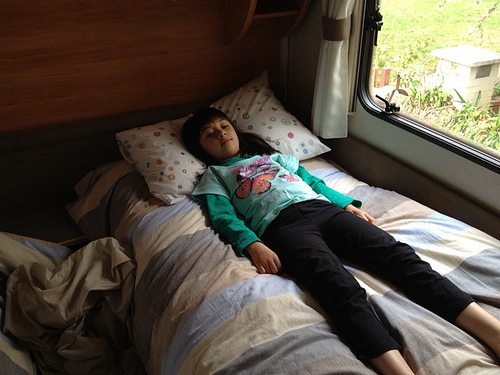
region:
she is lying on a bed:
[172, 100, 496, 366]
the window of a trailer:
[314, 4, 499, 197]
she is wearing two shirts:
[187, 137, 369, 279]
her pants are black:
[261, 193, 488, 373]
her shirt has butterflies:
[220, 163, 325, 211]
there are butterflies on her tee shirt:
[175, 93, 362, 303]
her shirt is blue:
[181, 130, 391, 279]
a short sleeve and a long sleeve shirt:
[173, 136, 363, 283]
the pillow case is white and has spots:
[122, 49, 333, 199]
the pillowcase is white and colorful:
[105, 47, 360, 216]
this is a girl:
[222, 130, 398, 255]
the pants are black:
[232, 232, 442, 374]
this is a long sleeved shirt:
[181, 103, 252, 295]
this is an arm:
[148, 195, 339, 312]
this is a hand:
[227, 238, 297, 303]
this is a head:
[150, 94, 254, 179]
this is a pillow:
[159, 151, 167, 180]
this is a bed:
[105, 231, 285, 372]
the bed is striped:
[199, 330, 237, 370]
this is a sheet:
[25, 230, 95, 327]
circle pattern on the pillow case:
[119, 78, 332, 203]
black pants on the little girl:
[268, 205, 475, 364]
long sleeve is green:
[201, 194, 260, 255]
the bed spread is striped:
[76, 159, 499, 374]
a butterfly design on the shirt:
[236, 172, 275, 198]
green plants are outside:
[377, 2, 499, 145]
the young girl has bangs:
[193, 109, 227, 134]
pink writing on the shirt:
[233, 156, 273, 180]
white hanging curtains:
[315, 1, 352, 137]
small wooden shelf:
[233, 0, 310, 41]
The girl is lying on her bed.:
[182, 108, 475, 374]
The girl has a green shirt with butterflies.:
[210, 157, 336, 202]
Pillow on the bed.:
[117, 124, 177, 159]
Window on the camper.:
[371, 3, 494, 151]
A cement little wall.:
[435, 44, 495, 111]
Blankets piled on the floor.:
[7, 232, 124, 370]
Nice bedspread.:
[166, 229, 245, 361]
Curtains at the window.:
[322, 3, 348, 142]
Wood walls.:
[8, 7, 225, 91]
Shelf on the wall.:
[231, 3, 311, 38]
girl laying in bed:
[180, 107, 490, 374]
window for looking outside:
[372, 1, 496, 167]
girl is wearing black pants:
[99, 86, 496, 349]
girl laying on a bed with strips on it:
[191, 101, 486, 371]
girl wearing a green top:
[190, 109, 497, 369]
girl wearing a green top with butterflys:
[183, 108, 498, 368]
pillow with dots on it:
[125, 75, 317, 200]